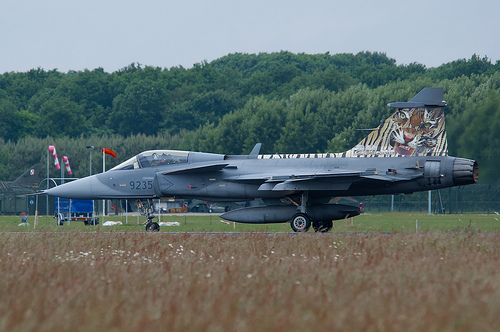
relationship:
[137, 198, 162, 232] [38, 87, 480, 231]
landing gear mounted on plane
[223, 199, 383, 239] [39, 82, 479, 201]
missles underneath plane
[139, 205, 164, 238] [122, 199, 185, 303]
landing gear and its assembly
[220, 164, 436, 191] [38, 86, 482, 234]
wing of  an jet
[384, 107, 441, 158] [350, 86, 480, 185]
tiger painted on tail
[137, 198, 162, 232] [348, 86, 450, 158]
landing gear has tail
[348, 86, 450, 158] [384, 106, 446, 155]
tail has tiger face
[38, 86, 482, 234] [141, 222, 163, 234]
jet has wheel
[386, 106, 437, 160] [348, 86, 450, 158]
tiger painted on tail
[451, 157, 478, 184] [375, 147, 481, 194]
nozzle of a jet engine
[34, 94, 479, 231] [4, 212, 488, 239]
jet on runway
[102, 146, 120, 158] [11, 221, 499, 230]
windsock on runway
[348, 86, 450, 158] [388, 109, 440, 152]
tail with image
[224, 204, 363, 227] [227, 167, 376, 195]
tank under wing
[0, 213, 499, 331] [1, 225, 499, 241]
grass along runway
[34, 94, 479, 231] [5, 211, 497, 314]
jet in grass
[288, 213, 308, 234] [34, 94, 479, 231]
wheel of jet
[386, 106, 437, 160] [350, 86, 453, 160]
tiger on tail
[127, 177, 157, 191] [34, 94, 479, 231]
number on jet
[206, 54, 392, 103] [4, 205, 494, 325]
tree behind field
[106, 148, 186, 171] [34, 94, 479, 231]
cockpit of jet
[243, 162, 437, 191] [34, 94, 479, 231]
wing of jet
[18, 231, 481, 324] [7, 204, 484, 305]
grass on field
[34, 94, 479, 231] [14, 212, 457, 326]
jet in field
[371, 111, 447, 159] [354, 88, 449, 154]
image on tail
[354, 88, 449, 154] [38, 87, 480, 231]
tail of plane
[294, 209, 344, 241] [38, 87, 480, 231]
landing gear of plane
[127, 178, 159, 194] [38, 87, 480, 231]
numbers on side of plane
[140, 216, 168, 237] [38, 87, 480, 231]
landing gear on plane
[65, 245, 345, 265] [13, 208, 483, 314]
flowers in field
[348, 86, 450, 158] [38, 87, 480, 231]
tail of plane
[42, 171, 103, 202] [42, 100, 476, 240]
nose of plane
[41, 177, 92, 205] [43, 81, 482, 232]
nosecone of jet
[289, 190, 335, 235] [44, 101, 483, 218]
landing gear of jet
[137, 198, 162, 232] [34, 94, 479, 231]
landing gear of jet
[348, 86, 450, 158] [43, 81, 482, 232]
tail of jet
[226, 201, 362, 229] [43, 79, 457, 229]
bomb of fighter jet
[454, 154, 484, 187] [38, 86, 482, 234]
tail thruster of jet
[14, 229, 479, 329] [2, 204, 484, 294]
bush in field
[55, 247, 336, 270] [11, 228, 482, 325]
flowers in bushes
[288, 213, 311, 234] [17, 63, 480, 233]
wheel on jet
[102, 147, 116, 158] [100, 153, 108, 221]
windsock on pole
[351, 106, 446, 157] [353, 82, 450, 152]
image on tail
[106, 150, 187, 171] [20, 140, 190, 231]
cockpit on front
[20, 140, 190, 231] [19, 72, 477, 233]
front of plane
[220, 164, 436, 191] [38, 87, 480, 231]
wing on plane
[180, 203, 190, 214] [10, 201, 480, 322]
barrel on ground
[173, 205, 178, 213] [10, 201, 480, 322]
barrel on ground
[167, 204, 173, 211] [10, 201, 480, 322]
barrel on ground